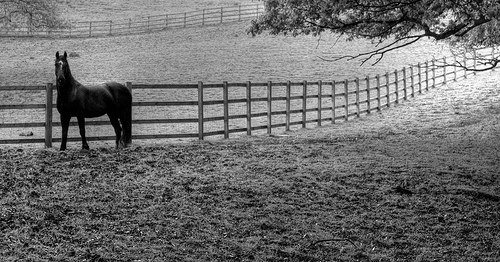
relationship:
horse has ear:
[48, 39, 141, 155] [51, 47, 62, 63]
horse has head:
[48, 39, 141, 155] [52, 46, 75, 90]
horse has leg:
[48, 39, 141, 155] [55, 106, 74, 155]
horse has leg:
[48, 39, 141, 155] [103, 106, 124, 155]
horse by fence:
[48, 39, 141, 155] [0, 36, 499, 160]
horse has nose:
[48, 39, 141, 155] [55, 74, 67, 89]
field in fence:
[2, 16, 500, 85] [1, 0, 271, 42]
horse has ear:
[48, 39, 141, 155] [60, 44, 71, 61]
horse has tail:
[48, 39, 141, 155] [117, 79, 140, 153]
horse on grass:
[48, 39, 141, 155] [0, 58, 500, 261]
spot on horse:
[57, 57, 65, 73] [48, 39, 141, 155]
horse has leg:
[48, 39, 141, 155] [75, 109, 94, 157]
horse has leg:
[48, 39, 141, 155] [122, 115, 131, 152]